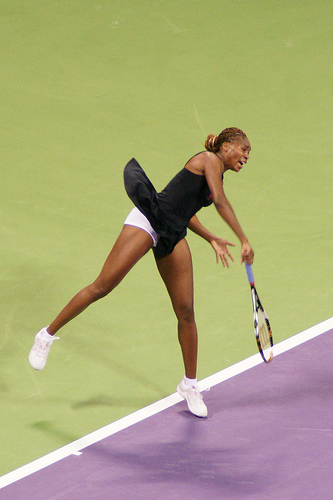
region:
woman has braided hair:
[181, 126, 243, 161]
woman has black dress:
[116, 152, 233, 244]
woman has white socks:
[38, 325, 54, 344]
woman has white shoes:
[29, 319, 63, 367]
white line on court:
[1, 322, 331, 499]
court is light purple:
[109, 410, 319, 478]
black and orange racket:
[249, 294, 284, 374]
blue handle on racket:
[244, 254, 263, 294]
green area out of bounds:
[97, 29, 168, 95]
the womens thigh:
[168, 258, 195, 289]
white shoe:
[177, 387, 207, 418]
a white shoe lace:
[201, 386, 211, 393]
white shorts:
[132, 212, 145, 225]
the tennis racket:
[255, 310, 275, 368]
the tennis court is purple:
[243, 435, 301, 483]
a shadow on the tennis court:
[138, 436, 265, 499]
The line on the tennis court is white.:
[0, 304, 332, 499]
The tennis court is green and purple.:
[0, 0, 332, 499]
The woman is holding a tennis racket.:
[24, 124, 278, 418]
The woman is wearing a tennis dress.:
[28, 121, 281, 423]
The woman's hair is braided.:
[13, 123, 279, 423]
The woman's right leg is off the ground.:
[25, 122, 287, 420]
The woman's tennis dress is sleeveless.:
[24, 123, 280, 419]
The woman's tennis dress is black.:
[27, 125, 278, 419]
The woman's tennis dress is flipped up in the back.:
[23, 122, 283, 421]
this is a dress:
[102, 126, 210, 266]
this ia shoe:
[25, 322, 60, 372]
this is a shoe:
[174, 374, 227, 418]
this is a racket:
[240, 262, 288, 375]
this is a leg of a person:
[23, 211, 153, 370]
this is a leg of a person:
[159, 255, 210, 414]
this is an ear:
[222, 139, 228, 152]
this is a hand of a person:
[204, 157, 261, 260]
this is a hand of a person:
[189, 216, 233, 265]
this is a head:
[195, 120, 273, 170]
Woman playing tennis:
[23, 117, 290, 424]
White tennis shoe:
[175, 375, 212, 421]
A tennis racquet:
[240, 260, 279, 381]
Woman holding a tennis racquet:
[32, 117, 300, 423]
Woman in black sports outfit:
[24, 111, 292, 429]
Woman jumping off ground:
[27, 98, 296, 420]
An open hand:
[205, 235, 237, 266]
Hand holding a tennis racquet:
[234, 239, 283, 370]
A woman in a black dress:
[28, 119, 278, 427]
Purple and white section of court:
[0, 311, 332, 496]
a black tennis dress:
[116, 146, 222, 260]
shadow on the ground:
[39, 395, 273, 493]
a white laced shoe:
[173, 374, 211, 418]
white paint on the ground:
[71, 447, 84, 458]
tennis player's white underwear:
[116, 199, 163, 246]